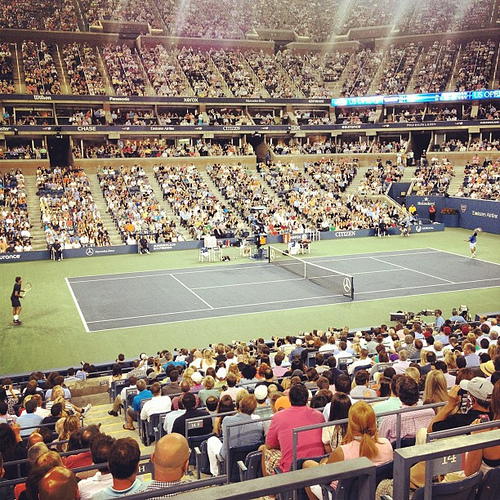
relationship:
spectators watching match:
[0, 326, 498, 497] [3, 221, 498, 375]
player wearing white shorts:
[466, 225, 484, 263] [465, 241, 479, 251]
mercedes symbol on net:
[266, 247, 277, 263] [262, 242, 357, 302]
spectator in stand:
[140, 432, 190, 494] [4, 313, 496, 497]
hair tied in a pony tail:
[339, 395, 384, 464] [355, 426, 381, 460]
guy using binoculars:
[429, 384, 491, 436] [453, 364, 494, 426]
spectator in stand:
[384, 374, 432, 436] [4, 313, 496, 497]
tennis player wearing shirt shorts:
[3, 275, 32, 329] [7, 295, 23, 308]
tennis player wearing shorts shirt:
[464, 219, 482, 266] [445, 197, 484, 317]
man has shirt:
[14, 276, 19, 357] [262, 407, 328, 474]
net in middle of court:
[257, 245, 359, 299] [0, 226, 499, 376]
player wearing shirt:
[466, 225, 484, 263] [470, 230, 478, 242]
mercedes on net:
[337, 270, 353, 300] [262, 242, 357, 302]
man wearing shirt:
[260, 383, 326, 473] [266, 403, 325, 471]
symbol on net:
[325, 264, 366, 317] [267, 246, 356, 301]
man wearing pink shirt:
[267, 405, 327, 472] [261, 404, 328, 472]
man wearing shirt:
[216, 393, 265, 474] [223, 415, 266, 456]